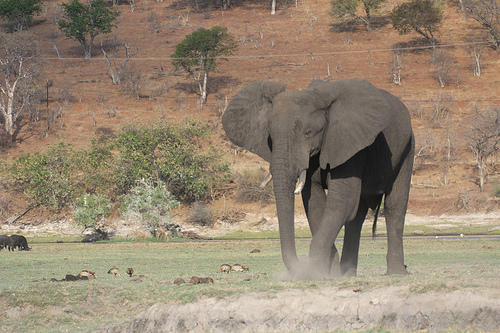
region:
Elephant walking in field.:
[211, 55, 445, 289]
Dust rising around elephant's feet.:
[270, 249, 362, 288]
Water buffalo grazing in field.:
[1, 228, 37, 260]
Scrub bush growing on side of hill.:
[12, 114, 231, 243]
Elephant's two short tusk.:
[253, 167, 318, 203]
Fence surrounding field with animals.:
[43, 46, 226, 103]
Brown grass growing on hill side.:
[229, 17, 416, 82]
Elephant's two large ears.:
[211, 76, 398, 169]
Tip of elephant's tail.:
[367, 218, 384, 240]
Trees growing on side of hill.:
[13, 0, 217, 97]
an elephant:
[215, 76, 437, 278]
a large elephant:
[213, 68, 452, 294]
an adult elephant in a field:
[224, 68, 436, 285]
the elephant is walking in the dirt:
[218, 57, 433, 287]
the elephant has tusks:
[219, 76, 432, 276]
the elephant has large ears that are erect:
[213, 68, 445, 283]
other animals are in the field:
[3, 223, 268, 289]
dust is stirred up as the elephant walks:
[213, 71, 455, 304]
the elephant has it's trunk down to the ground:
[217, 66, 431, 273]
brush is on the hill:
[29, 7, 496, 212]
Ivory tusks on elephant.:
[256, 157, 362, 258]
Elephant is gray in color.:
[231, 113, 421, 261]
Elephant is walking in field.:
[267, 139, 405, 241]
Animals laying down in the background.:
[55, 257, 272, 318]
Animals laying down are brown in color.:
[78, 270, 305, 309]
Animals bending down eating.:
[8, 221, 49, 274]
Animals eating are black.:
[2, 220, 74, 297]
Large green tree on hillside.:
[26, 140, 246, 232]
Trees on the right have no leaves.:
[417, 97, 495, 192]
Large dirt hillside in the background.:
[73, 103, 483, 222]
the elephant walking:
[223, 71, 440, 278]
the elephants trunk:
[255, 99, 327, 308]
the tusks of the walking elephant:
[254, 171, 348, 210]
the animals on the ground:
[69, 268, 259, 295]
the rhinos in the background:
[1, 234, 48, 263]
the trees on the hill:
[126, 51, 227, 192]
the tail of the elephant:
[364, 211, 384, 242]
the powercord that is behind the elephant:
[26, 43, 385, 66]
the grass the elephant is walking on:
[426, 246, 478, 270]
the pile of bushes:
[27, 121, 187, 216]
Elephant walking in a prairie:
[215, 68, 416, 279]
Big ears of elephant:
[220, 78, 391, 160]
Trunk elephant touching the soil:
[265, 160, 295, 280]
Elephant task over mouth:
[290, 161, 310, 191]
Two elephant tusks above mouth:
[255, 165, 310, 190]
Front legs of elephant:
[302, 168, 354, 279]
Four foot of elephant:
[301, 256, 412, 278]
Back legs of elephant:
[340, 170, 420, 280]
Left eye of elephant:
[300, 125, 315, 140]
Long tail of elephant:
[368, 196, 385, 240]